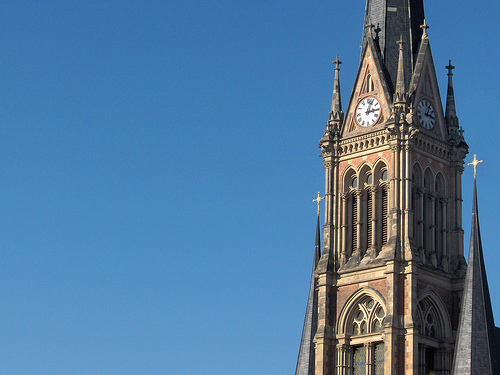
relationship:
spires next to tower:
[296, 153, 498, 374] [294, 2, 496, 374]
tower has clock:
[294, 2, 496, 374] [354, 95, 383, 128]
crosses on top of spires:
[311, 154, 486, 217] [296, 153, 498, 374]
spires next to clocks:
[317, 15, 467, 147] [351, 96, 437, 132]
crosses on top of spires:
[331, 19, 458, 76] [296, 153, 498, 374]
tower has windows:
[294, 2, 496, 374] [337, 163, 449, 374]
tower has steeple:
[294, 2, 496, 374] [352, 0, 435, 41]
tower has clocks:
[294, 2, 496, 374] [351, 96, 437, 132]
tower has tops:
[294, 2, 496, 374] [320, 2, 466, 162]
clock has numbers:
[354, 95, 383, 128] [354, 96, 381, 127]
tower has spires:
[294, 2, 496, 374] [317, 15, 467, 147]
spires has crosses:
[317, 15, 467, 147] [331, 19, 458, 76]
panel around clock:
[341, 37, 395, 139] [354, 95, 383, 128]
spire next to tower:
[452, 153, 499, 374] [294, 2, 496, 374]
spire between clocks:
[391, 33, 410, 99] [351, 96, 437, 132]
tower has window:
[294, 2, 496, 374] [337, 288, 386, 375]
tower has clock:
[294, 2, 496, 374] [416, 98, 438, 131]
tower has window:
[294, 2, 496, 374] [412, 285, 452, 374]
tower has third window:
[294, 2, 496, 374] [342, 159, 392, 258]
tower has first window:
[294, 2, 496, 374] [337, 288, 386, 375]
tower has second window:
[294, 2, 496, 374] [412, 285, 452, 374]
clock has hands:
[354, 95, 383, 128] [364, 98, 381, 117]